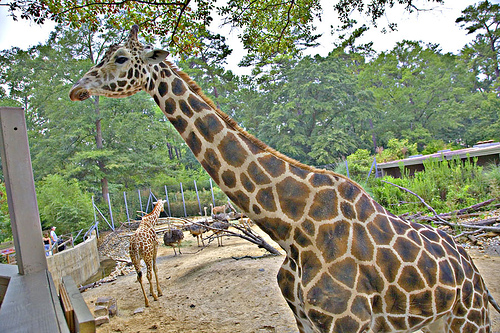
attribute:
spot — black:
[313, 217, 350, 262]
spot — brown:
[351, 222, 376, 260]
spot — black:
[383, 282, 408, 314]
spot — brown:
[216, 130, 248, 167]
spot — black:
[419, 232, 446, 259]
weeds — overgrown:
[384, 170, 480, 215]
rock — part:
[147, 316, 165, 330]